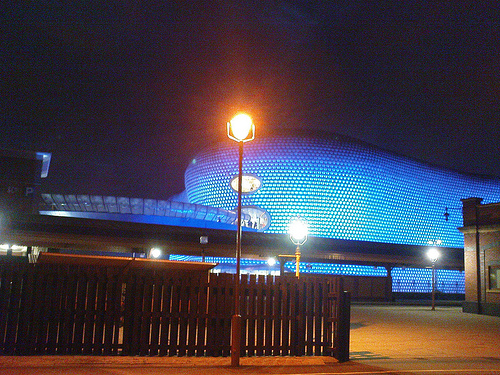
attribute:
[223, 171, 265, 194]
light — bright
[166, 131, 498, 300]
building — blue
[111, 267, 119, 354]
pole — wood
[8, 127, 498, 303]
building — blue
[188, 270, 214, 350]
pole — wood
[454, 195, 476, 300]
corner building — brick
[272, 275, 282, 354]
pole — wooden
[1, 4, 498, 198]
sky — dark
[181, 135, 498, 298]
patterned brickwork — honeycomb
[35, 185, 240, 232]
cover — glass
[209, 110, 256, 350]
street lamp — small, orange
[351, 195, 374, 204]
light — bright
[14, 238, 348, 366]
fence — wood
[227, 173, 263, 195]
window — large, oval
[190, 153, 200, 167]
light — bright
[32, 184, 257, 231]
stage — blue, glass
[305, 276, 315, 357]
pole — wood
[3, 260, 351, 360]
fence — short, dark brown, wooden, wood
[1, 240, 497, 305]
walkway — covered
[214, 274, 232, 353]
pole — wood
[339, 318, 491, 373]
reflection — light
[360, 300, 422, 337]
pavement — illuminated, white, smooth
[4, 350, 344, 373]
curb — sloped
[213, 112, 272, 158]
light — glowing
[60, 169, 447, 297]
structure — modern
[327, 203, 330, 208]
light — bright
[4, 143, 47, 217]
building — cement, brick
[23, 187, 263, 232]
hallway — blue, glass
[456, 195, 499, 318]
building — red brick, stone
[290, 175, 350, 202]
light — bright